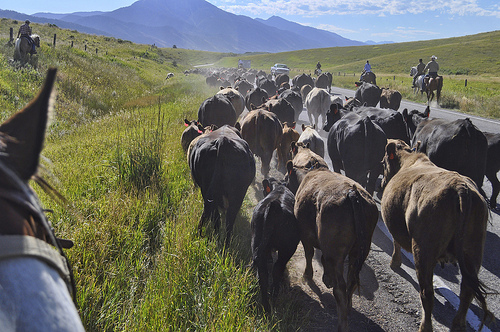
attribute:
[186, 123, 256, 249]
cow — black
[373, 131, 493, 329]
cow — brown 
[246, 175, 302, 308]
cow — small, black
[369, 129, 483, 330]
cow — brown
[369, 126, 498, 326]
cow — black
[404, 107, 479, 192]
cow — black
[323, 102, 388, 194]
cow — black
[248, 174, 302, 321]
cow — black